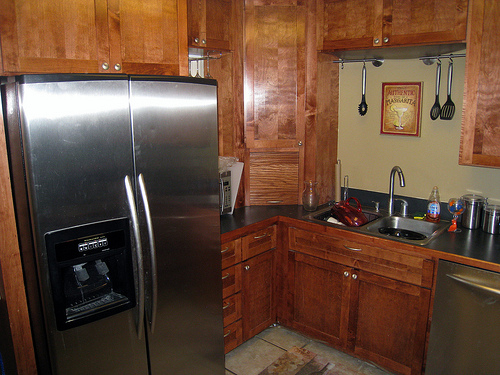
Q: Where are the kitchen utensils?
A: Hanging above the sink.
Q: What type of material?
A: Wood.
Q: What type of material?
A: Metal.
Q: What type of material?
A: Metal.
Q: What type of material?
A: Wood.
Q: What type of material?
A: Metal.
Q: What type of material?
A: Metal.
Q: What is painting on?
A: Wall.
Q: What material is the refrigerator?
A: Stainless steel.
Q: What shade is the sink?
A: Silver.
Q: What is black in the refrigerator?
A: The dispenser.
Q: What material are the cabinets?
A: Wood.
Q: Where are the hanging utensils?
A: Above the sink.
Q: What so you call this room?
A: A kitchen.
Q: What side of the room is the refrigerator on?
A: The left.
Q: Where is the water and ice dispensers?
A: On the refrigerator.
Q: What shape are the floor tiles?
A: Square.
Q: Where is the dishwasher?
A: On the right side of the sink.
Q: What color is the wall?
A: Brown.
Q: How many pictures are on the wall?
A: One.